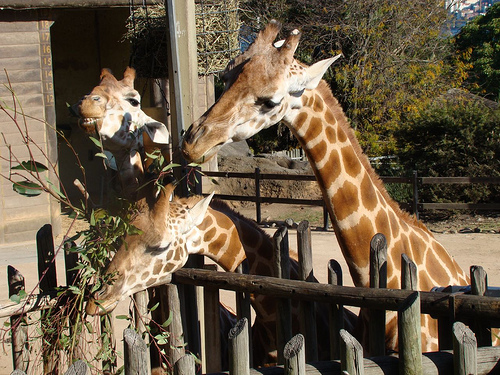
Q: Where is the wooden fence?
A: In front of the giraffes.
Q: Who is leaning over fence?
A: The giraffe.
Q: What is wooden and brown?
A: The fence.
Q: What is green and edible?
A: The leaves.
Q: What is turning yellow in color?
A: The leaves.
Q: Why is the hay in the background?
A: For eating.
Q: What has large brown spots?
A: The giraffes.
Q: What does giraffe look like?
A: Brown and spotted.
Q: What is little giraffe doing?
A: Leaning over fence.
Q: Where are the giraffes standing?
A: By a building.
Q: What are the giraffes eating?
A: Leaves.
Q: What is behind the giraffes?
A: Trees.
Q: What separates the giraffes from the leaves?
A: A fence.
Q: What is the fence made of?
A: Wood.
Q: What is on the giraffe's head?
A: Horns.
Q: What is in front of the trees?
A: Black fence.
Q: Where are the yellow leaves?
A: In the trees.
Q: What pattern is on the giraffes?
A: Brown and tan spots.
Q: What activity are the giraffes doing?
A: Eating.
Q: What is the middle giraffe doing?
A: Eating leaves.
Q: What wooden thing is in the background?
A: Fence.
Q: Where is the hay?
A: High in a cage.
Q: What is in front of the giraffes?
A: Wooden fence.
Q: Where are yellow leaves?
A: Tree.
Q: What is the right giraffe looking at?
A: Other giraffe's head.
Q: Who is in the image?
A: There are no people in the image.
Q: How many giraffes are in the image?
A: Three.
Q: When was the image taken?
A: During the day.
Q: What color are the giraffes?
A: Brown.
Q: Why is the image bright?
A: The sun is shining.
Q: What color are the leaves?
A: Green.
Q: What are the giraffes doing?
A: Eating.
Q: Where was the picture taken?
A: In a zoo.